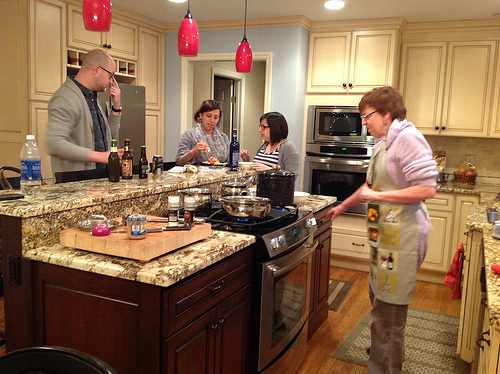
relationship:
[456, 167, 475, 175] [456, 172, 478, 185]
fruits in basket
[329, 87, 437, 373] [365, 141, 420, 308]
woman wearing apron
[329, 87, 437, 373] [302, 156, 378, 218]
woman by stove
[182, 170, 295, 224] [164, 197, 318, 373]
pots on stove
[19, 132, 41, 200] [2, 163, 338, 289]
bottle on counters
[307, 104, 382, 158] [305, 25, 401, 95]
microwave under cabinet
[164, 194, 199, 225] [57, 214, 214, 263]
spices on board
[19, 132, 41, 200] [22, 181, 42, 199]
bottle of water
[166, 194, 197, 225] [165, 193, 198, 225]
pair of seasonings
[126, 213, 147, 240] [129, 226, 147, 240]
jar of cheese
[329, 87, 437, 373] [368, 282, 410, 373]
woman has jeans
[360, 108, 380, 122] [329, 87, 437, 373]
glasses on woman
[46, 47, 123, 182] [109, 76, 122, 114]
guy has hand